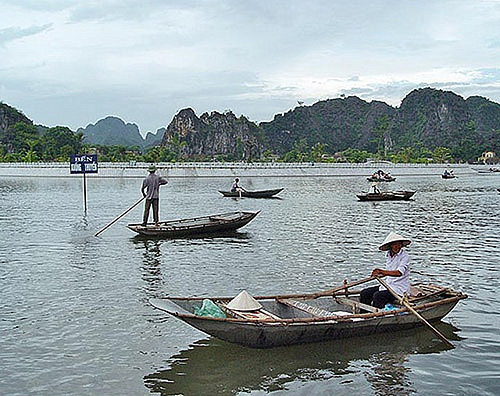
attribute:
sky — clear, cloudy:
[2, 2, 495, 88]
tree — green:
[341, 144, 367, 165]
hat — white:
[229, 289, 261, 313]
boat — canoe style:
[147, 284, 470, 346]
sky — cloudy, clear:
[0, 3, 495, 140]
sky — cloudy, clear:
[22, 11, 497, 143]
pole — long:
[82, 182, 149, 252]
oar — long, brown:
[373, 275, 455, 345]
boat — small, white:
[352, 177, 417, 203]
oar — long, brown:
[88, 189, 173, 246]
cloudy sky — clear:
[162, 16, 274, 86]